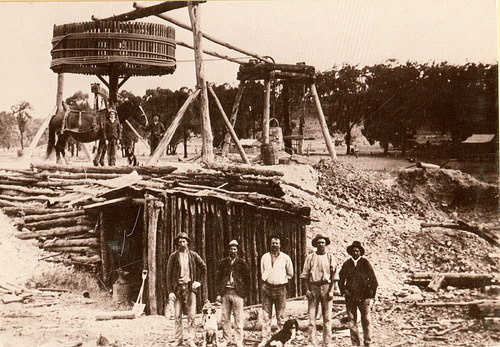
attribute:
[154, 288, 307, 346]
dog — standing, looking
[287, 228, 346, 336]
man — standing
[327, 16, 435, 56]
sky — clear, gray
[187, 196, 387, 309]
men — wearing, group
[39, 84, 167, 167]
horse — distance, black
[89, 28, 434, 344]
photo — black, white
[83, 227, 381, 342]
people — group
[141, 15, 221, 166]
log — shack, covered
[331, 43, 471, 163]
tree — background, long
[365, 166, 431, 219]
ground — rocky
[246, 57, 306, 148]
tower — wooden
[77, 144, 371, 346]
shaft — mine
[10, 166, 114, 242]
timber — scattered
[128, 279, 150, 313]
shovel — leaning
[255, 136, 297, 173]
barrel — wooden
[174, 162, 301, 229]
contraption — wooden